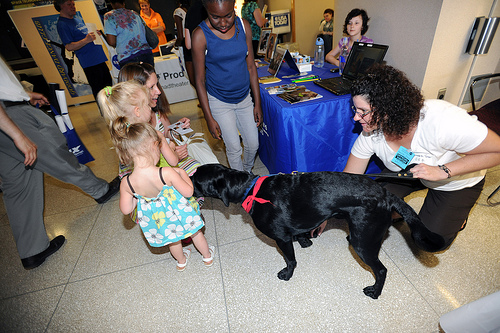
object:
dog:
[189, 163, 446, 299]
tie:
[239, 174, 271, 216]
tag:
[390, 145, 414, 170]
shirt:
[349, 99, 488, 191]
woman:
[310, 65, 500, 253]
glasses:
[351, 104, 381, 118]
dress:
[126, 168, 205, 248]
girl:
[108, 116, 216, 272]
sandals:
[202, 245, 216, 265]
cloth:
[251, 58, 385, 181]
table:
[255, 59, 356, 171]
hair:
[349, 63, 424, 140]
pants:
[0, 105, 109, 260]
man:
[0, 56, 121, 270]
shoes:
[21, 234, 63, 270]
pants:
[373, 176, 484, 254]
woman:
[325, 7, 374, 68]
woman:
[117, 62, 205, 224]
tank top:
[203, 15, 252, 104]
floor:
[0, 100, 499, 332]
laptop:
[313, 41, 387, 97]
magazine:
[277, 84, 325, 106]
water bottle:
[313, 37, 324, 69]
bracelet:
[437, 163, 453, 178]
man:
[52, 0, 111, 117]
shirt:
[56, 16, 108, 69]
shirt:
[139, 9, 168, 52]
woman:
[135, 0, 168, 58]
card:
[168, 121, 193, 137]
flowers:
[149, 210, 165, 229]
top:
[316, 37, 325, 45]